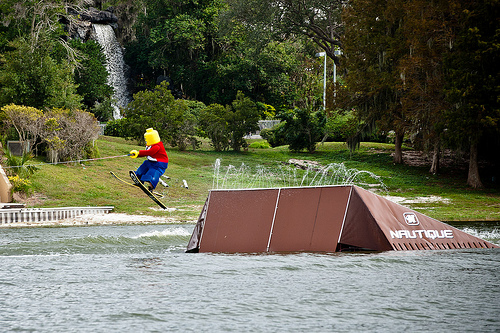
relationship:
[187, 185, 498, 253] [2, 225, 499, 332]
ramp in water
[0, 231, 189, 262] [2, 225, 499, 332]
wake in water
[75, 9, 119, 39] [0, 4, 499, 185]
rock behind trees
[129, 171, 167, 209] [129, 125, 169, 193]
skis under skier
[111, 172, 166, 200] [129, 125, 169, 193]
skis under skier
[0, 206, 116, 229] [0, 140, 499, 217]
wall on shore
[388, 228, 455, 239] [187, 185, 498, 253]
word on side of ramp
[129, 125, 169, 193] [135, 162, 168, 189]
skier wearing pants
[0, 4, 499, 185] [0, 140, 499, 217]
trees on shore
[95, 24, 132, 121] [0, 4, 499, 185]
waterfall between trees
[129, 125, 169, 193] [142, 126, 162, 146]
skier wearing bucket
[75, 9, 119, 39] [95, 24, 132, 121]
rock above waterfall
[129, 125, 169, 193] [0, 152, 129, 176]
skier holding rope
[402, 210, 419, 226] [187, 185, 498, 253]
logo on side of ramp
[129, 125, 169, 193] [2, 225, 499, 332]
skier above water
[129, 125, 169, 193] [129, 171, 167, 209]
skier on skis